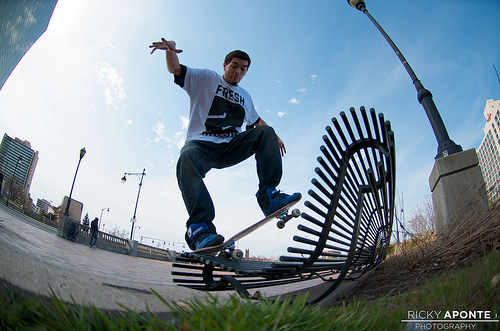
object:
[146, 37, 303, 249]
man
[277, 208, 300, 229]
wheels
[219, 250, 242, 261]
wheels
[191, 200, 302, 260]
skateboard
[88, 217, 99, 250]
person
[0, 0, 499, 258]
sky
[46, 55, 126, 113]
cloud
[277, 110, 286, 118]
cloud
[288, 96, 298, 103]
cloud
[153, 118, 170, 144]
cloud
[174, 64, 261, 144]
shirt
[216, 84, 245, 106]
writing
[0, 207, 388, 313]
sidewalk